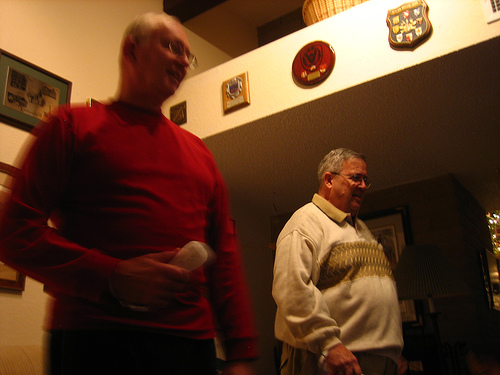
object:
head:
[113, 12, 196, 104]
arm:
[0, 122, 118, 297]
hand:
[123, 252, 191, 307]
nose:
[180, 54, 190, 68]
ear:
[125, 35, 137, 63]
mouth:
[168, 70, 182, 86]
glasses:
[140, 33, 197, 54]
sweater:
[274, 196, 407, 349]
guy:
[273, 149, 406, 373]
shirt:
[12, 88, 251, 339]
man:
[0, 14, 263, 371]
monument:
[290, 41, 335, 91]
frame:
[0, 50, 72, 136]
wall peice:
[219, 72, 253, 112]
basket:
[300, 0, 361, 28]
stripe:
[321, 246, 395, 281]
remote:
[175, 239, 206, 273]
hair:
[124, 9, 186, 38]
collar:
[312, 192, 351, 222]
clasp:
[106, 259, 124, 304]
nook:
[180, 0, 269, 58]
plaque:
[382, 0, 431, 52]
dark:
[433, 289, 492, 373]